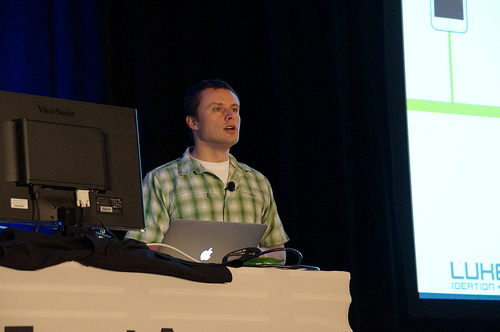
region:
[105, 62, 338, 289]
young man wearing a green plaid shirt doing a presentation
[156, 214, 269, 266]
the front of an apple mac laptop computer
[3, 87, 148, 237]
the back of a large View Sonic monitor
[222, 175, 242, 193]
a black microphone pinned to the man's shirt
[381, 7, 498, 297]
large screen where the presentation is projected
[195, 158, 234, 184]
white t-shirt under the man's green plaid button-down shirt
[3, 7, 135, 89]
large blue drapes behind the man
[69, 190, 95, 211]
white monitor cord attachment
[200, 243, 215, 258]
apple logo on the back of the laptop screen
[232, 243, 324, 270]
black cords from the computers on the desk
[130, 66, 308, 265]
a man wearing a stripped shirt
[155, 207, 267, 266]
an apple laptop being used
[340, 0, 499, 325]
a large projectile display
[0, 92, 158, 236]
a widescreen lcd display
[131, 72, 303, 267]
the guy is giving a presentation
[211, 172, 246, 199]
a microphone is on the guys shirt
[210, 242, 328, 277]
lots of cables on the balcony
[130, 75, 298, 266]
the person is of white ethnicity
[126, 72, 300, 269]
a short hair male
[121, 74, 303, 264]
this person wearing a white shirt underneath his shirt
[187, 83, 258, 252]
man at a computer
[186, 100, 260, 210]
man in a green shirt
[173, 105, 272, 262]
man with a Apple Computer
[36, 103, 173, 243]
black computer monitor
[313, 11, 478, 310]
a large display screen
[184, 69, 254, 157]
Guy with black hair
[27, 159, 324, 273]
cords on back of computer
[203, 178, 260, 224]
microphone attached to mans shirt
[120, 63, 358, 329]
man standing at a podium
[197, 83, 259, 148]
white man with blue eyes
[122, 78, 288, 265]
the man in front of the laptop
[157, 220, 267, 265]
the opened laptop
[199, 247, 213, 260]
the lit up apple logo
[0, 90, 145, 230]
the back of a monitor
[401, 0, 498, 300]
the large screen next to the man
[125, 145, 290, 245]
the buttoned up shirt on the man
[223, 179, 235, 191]
the microphone on the man's shirt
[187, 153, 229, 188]
the shirt under the man's button up shirt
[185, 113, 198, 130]
the ear on the man's head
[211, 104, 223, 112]
the eye on the man's face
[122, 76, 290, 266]
guy wearing plaid shirt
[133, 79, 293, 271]
a guy wearing a green plaid shirt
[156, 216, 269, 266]
an apple computer on the desk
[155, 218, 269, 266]
a laptop on the desk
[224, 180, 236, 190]
a microphone on attached to the guy's shirt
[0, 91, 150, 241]
a back of the monitor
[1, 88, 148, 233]
a back part of the monitor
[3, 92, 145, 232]
a back part of the black monitor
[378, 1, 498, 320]
a big screen on the side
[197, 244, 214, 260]
an apple logo of the laptop